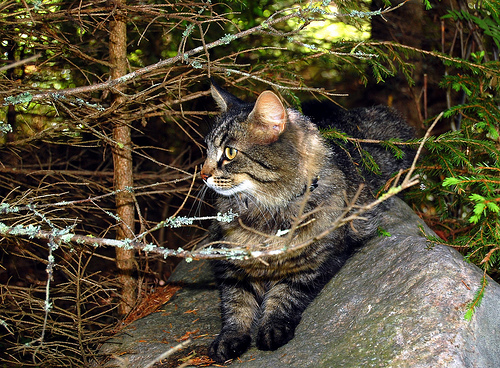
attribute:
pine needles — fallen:
[460, 276, 495, 321]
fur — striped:
[199, 84, 320, 201]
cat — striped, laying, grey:
[173, 79, 413, 360]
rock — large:
[373, 236, 497, 364]